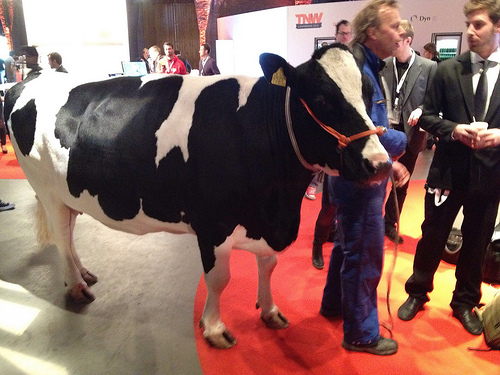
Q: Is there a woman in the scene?
A: No, there are no women.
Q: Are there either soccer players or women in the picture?
A: No, there are no women or soccer players.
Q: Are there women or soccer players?
A: No, there are no women or soccer players.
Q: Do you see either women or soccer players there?
A: No, there are no women or soccer players.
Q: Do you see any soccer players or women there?
A: No, there are no women or soccer players.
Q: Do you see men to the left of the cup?
A: Yes, there is a man to the left of the cup.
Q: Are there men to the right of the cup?
A: No, the man is to the left of the cup.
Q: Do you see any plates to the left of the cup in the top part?
A: No, there is a man to the left of the cup.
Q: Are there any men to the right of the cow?
A: Yes, there is a man to the right of the cow.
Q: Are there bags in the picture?
A: No, there are no bags.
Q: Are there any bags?
A: No, there are no bags.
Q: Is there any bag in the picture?
A: No, there are no bags.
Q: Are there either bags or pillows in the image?
A: No, there are no bags or pillows.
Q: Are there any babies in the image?
A: No, there are no babies.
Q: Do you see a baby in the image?
A: No, there are no babies.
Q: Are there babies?
A: No, there are no babies.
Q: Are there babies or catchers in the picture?
A: No, there are no babies or catchers.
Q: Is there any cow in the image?
A: Yes, there is a cow.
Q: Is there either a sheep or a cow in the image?
A: Yes, there is a cow.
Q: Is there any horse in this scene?
A: No, there are no horses.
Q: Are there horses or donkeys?
A: No, there are no horses or donkeys.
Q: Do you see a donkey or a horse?
A: No, there are no horses or donkeys.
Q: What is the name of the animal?
A: The animal is a cow.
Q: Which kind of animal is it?
A: The animal is a cow.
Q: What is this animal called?
A: This is a cow.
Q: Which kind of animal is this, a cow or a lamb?
A: This is a cow.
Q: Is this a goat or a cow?
A: This is a cow.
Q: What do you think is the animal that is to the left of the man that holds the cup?
A: The animal is a cow.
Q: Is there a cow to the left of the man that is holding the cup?
A: Yes, there is a cow to the left of the man.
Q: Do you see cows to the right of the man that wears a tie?
A: No, the cow is to the left of the man.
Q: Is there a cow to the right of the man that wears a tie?
A: No, the cow is to the left of the man.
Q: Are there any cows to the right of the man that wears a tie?
A: No, the cow is to the left of the man.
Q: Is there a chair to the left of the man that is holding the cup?
A: No, there is a cow to the left of the man.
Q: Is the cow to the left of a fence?
A: No, the cow is to the left of a man.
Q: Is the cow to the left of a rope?
A: No, the cow is to the left of a man.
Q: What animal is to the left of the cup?
A: The animal is a cow.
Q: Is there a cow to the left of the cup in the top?
A: Yes, there is a cow to the left of the cup.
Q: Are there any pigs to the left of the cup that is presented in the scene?
A: No, there is a cow to the left of the cup.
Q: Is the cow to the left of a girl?
A: No, the cow is to the left of a cup.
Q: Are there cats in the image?
A: No, there are no cats.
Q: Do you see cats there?
A: No, there are no cats.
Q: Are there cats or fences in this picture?
A: No, there are no cats or fences.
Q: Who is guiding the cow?
A: The man is guiding the cow.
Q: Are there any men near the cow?
A: Yes, there is a man near the cow.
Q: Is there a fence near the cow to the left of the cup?
A: No, there is a man near the cow.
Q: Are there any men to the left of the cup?
A: Yes, there is a man to the left of the cup.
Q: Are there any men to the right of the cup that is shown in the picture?
A: No, the man is to the left of the cup.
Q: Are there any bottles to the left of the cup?
A: No, there is a man to the left of the cup.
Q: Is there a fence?
A: No, there are no fences.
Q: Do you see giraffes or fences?
A: No, there are no fences or giraffes.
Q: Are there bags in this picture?
A: No, there are no bags.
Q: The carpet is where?
A: The carpet is on the floor.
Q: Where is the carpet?
A: The carpet is on the floor.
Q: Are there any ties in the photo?
A: Yes, there is a tie.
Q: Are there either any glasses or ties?
A: Yes, there is a tie.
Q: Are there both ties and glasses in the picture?
A: No, there is a tie but no glasses.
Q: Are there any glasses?
A: No, there are no glasses.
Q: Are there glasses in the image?
A: No, there are no glasses.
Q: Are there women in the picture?
A: No, there are no women.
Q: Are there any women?
A: No, there are no women.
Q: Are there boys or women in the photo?
A: No, there are no women or boys.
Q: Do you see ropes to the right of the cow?
A: No, there is a man to the right of the cow.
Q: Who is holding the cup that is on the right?
A: The man is holding the cup.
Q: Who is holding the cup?
A: The man is holding the cup.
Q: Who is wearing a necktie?
A: The man is wearing a necktie.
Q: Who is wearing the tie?
A: The man is wearing a necktie.